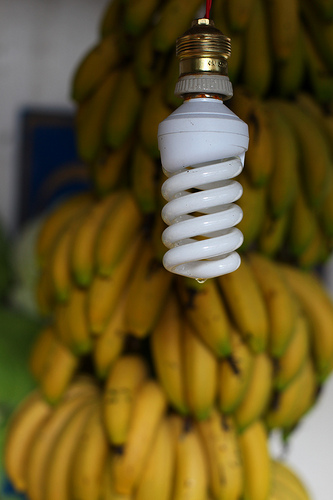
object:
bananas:
[0, 0, 333, 498]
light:
[156, 17, 248, 284]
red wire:
[204, 0, 213, 20]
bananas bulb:
[54, 209, 301, 423]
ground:
[236, 115, 249, 155]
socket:
[176, 17, 231, 81]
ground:
[279, 97, 300, 119]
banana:
[150, 290, 194, 416]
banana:
[197, 403, 243, 498]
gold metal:
[176, 14, 232, 77]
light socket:
[175, 17, 230, 76]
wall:
[34, 7, 98, 44]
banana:
[102, 340, 150, 456]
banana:
[170, 430, 209, 499]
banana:
[277, 259, 333, 387]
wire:
[203, 0, 212, 20]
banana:
[71, 190, 119, 291]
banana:
[109, 375, 168, 498]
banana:
[103, 347, 150, 453]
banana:
[241, 419, 273, 499]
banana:
[181, 315, 217, 420]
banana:
[95, 194, 141, 276]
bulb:
[158, 94, 250, 285]